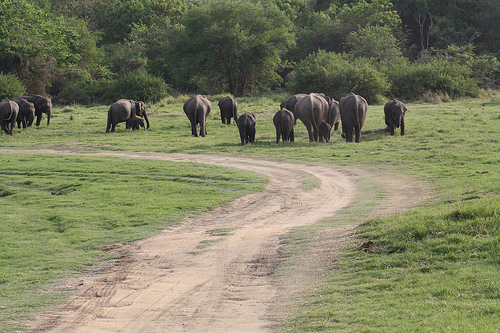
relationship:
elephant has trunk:
[33, 95, 53, 127] [45, 108, 52, 124]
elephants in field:
[5, 87, 412, 147] [4, 92, 499, 329]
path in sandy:
[0, 144, 430, 331] [0, 140, 438, 327]